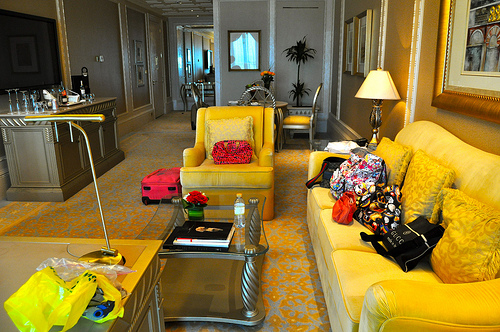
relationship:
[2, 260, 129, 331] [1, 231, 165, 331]
bag on counter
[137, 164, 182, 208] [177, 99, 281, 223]
bag next to chair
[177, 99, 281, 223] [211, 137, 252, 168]
chair with bag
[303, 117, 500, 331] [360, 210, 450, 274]
couch with purses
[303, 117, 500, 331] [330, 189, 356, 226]
couch with purses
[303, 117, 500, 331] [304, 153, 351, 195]
couch with purses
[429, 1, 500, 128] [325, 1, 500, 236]
picture on wall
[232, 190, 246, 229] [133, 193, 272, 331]
bottle on coffee table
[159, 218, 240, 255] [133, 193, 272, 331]
books on coffee table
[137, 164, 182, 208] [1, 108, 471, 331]
bag on floor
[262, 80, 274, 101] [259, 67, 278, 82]
vase of flowers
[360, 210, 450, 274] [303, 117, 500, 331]
purses on couch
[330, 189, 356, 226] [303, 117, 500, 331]
purses on couch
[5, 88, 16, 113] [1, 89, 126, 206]
glasses on bar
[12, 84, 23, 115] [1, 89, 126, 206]
glasses on bar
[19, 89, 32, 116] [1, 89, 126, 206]
glasses on bar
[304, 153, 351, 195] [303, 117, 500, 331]
purses on couch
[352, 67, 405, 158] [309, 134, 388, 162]
lamp on table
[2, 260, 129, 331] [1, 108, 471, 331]
bag on floor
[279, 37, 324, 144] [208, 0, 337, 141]
plant against wall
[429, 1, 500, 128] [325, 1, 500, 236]
picture hanging on wall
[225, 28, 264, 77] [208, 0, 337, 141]
mirror on wall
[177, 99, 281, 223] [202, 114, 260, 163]
chair with pillow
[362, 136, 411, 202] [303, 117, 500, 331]
pillow on couch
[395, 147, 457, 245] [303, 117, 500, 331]
pillow on couch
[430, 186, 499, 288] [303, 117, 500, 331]
pillow on couch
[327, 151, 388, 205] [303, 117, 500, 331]
bag on couch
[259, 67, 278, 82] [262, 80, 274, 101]
flowers in vase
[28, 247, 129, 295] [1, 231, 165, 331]
plastic on counter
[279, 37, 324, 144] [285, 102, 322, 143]
plant in pot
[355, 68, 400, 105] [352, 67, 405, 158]
shade of lamp